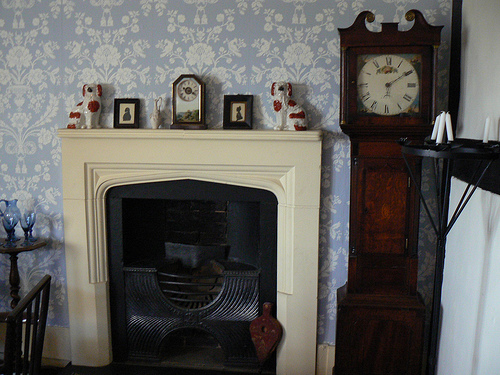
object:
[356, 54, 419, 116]
face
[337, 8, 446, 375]
clock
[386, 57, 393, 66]
numerial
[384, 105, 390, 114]
numerial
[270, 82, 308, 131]
figurine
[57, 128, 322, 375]
fireplace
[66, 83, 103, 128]
figurine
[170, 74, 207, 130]
clcok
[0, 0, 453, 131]
wall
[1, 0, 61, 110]
pattern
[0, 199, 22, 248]
vase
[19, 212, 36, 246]
cup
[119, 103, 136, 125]
picture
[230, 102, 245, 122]
picture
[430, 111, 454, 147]
candle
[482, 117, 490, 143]
candle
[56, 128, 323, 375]
mantle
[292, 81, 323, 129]
shadow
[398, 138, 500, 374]
pole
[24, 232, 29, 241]
stem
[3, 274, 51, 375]
chair